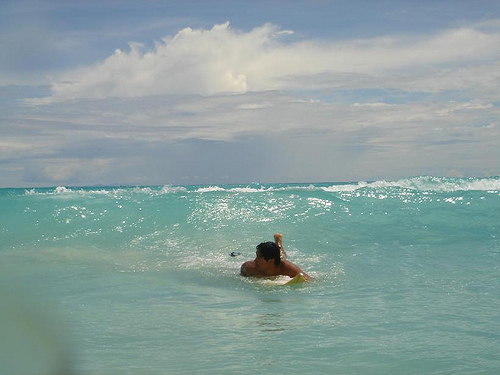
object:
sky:
[1, 3, 497, 188]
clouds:
[19, 19, 498, 141]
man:
[239, 231, 311, 284]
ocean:
[0, 177, 499, 374]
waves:
[4, 175, 498, 231]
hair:
[255, 240, 281, 263]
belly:
[258, 274, 287, 278]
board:
[270, 273, 306, 289]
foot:
[274, 232, 283, 242]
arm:
[291, 269, 311, 282]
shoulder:
[241, 260, 300, 276]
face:
[255, 252, 269, 271]